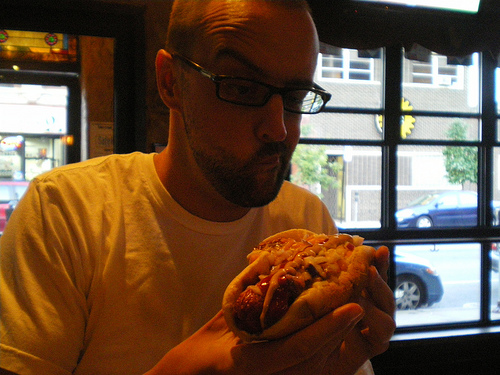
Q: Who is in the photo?
A: A man eating.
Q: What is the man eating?
A: A hotdog.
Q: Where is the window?
A: Behind the man.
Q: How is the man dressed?
A: In a yellow T-shirt.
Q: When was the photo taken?
A: While the man was eating.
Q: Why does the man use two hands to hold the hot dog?
A: It's sloppy.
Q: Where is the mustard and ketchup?
A: On the hotdog.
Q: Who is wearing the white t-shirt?
A: The man.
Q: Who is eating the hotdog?
A: The man.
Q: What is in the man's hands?
A: Hot Dog.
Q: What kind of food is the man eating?
A: Hotdog.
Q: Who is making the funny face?
A: The man.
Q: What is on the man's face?
A: Black glasses.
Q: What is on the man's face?
A: A beard.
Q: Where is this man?
A: Restaurant.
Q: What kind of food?
A: Chili dog.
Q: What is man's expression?
A: Confused.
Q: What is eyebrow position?
A: Raised.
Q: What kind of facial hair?
A: Beard.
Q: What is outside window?
A: Street.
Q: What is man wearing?
A: Glasses.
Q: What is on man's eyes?
A: Glasses.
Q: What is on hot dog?
A: Cheese.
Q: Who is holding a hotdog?
A: A man.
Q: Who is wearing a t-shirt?
A: A man.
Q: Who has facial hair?
A: A man.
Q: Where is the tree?
A: Outside the building.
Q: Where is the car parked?
A: On the side of the road.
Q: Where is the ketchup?
A: On the hotdog.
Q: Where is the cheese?
A: On the hotdog.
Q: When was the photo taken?
A: Daytime.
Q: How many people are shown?
A: One.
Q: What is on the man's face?
A: Glasses.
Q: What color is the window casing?
A: Black.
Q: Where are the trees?
A: Across the street.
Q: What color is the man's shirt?
A: Yellow.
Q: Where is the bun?
A: Man's hand.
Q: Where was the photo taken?
A: In a restaurant.